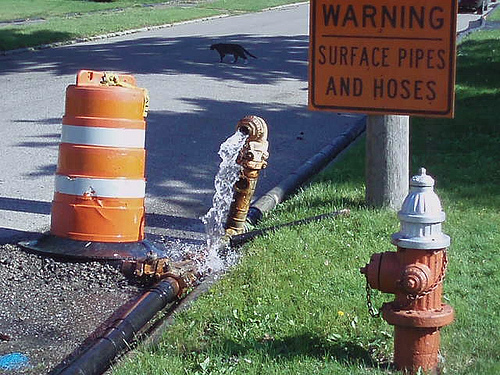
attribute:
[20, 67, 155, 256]
cone — large, orange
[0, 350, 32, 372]
painted dot — blue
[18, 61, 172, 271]
cone — orange, white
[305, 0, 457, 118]
warning sign — orange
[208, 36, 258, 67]
cat — black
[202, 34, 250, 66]
cat — black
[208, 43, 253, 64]
cat — black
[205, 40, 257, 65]
cat — black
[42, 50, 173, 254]
cone — orange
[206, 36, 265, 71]
cat — black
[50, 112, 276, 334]
water — broken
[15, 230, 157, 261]
rubber base — black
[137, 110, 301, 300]
pipes — burst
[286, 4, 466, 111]
sign — orange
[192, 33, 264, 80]
cat — dark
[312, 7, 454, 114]
sign — orange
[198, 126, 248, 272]
water — gushing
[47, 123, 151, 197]
stripes — white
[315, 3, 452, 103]
writing — black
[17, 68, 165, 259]
cone — orange, white, caution